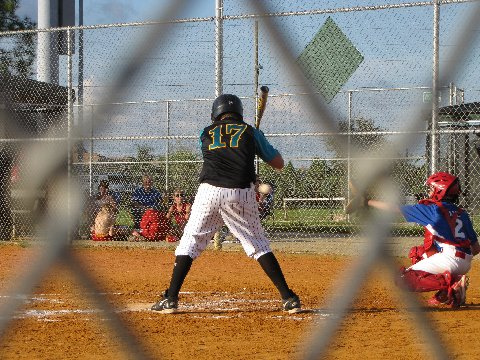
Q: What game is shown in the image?
A: Baseball.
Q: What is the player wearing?
A: White pants.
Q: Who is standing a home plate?
A: A batter.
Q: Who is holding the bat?
A: Baseball player.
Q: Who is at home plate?
A: Catcher.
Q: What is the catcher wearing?
A: Baseball mitt.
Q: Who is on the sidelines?
A: Spectators.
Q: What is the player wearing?
A: Blue and white jersey.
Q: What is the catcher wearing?
A: Red equipment.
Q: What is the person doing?
A: Playing baseball.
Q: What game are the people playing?
A: Baseball.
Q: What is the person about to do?
A: It the ball.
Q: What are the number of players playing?
A: Tow.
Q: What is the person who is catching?
A: A person.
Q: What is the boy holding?
A: Bat.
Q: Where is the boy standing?
A: Batters box.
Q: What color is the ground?
A: Brown.